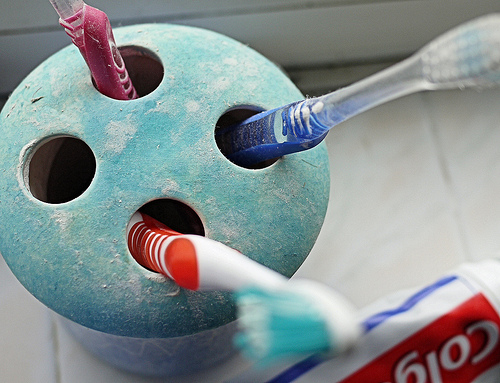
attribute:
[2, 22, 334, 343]
toothbrush holder — blue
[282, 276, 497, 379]
tube — blue, white, red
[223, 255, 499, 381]
toothpaste — red, white, blue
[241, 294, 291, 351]
bristles — blue, white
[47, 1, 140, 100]
toothbrush handle — maroon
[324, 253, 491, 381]
tube — Colgate, toothpaste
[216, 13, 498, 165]
toothbrush — plastic, clear, blue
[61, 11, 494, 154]
toothbrush — purple, clear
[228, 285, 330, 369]
bristles — white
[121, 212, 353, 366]
toothbrush — white, red, blue, orange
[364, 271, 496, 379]
tube — toothpaste, red, white, blue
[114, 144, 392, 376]
toothbrush — blue, clear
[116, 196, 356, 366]
toothbrush — green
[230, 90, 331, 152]
handle — blue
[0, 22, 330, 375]
toothbrush holder — ceramic, green, light blue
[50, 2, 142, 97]
toothbrush — plastic, clear, magenta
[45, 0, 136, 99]
toothbrush — purple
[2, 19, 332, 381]
holder — toothbrush